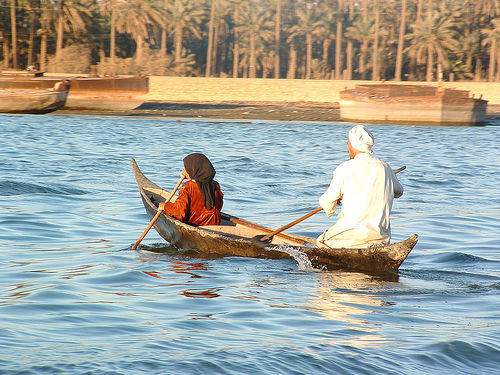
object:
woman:
[157, 153, 224, 226]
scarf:
[183, 153, 217, 209]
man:
[316, 124, 403, 248]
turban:
[347, 124, 375, 154]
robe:
[317, 152, 403, 247]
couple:
[157, 124, 404, 249]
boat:
[121, 153, 439, 286]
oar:
[131, 173, 186, 249]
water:
[0, 113, 499, 374]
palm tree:
[273, 4, 281, 79]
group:
[5, 0, 499, 83]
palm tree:
[401, 9, 462, 81]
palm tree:
[344, 17, 388, 82]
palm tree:
[205, 0, 215, 78]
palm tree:
[394, 0, 406, 82]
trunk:
[394, 60, 402, 80]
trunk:
[425, 67, 434, 82]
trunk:
[358, 64, 365, 79]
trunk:
[274, 65, 279, 78]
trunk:
[204, 64, 211, 77]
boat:
[0, 78, 72, 114]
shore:
[0, 70, 498, 123]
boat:
[58, 72, 153, 117]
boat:
[318, 81, 489, 128]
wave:
[416, 251, 498, 266]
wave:
[0, 177, 103, 197]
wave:
[210, 155, 263, 165]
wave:
[0, 340, 497, 372]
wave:
[399, 177, 465, 185]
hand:
[180, 168, 189, 178]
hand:
[157, 202, 165, 210]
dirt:
[109, 100, 499, 123]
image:
[1, 0, 499, 373]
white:
[307, 120, 404, 248]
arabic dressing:
[157, 149, 228, 224]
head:
[179, 150, 219, 190]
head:
[342, 125, 383, 158]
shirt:
[162, 179, 227, 226]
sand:
[0, 72, 499, 105]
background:
[1, 1, 499, 128]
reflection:
[137, 255, 416, 366]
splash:
[264, 243, 327, 272]